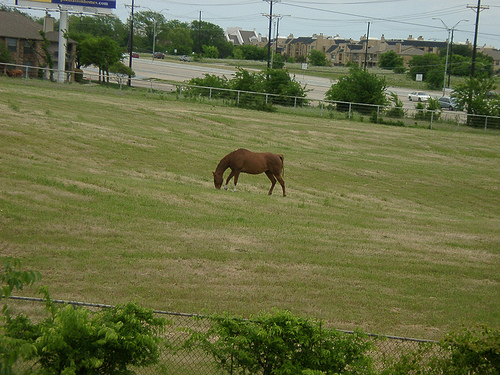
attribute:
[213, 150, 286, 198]
horse — grazing, standing, brown, eating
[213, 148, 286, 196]
animal — brown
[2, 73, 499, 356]
field — green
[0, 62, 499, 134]
fence — gray, chain link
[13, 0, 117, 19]
sign — white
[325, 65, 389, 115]
bush — green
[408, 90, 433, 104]
car — white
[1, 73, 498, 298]
grass — green, short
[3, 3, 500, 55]
sky — overcast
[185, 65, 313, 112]
bushes — growing